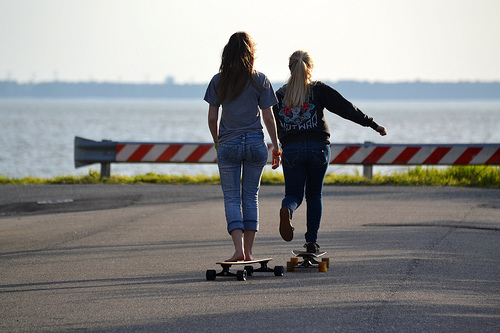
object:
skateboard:
[203, 257, 285, 282]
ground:
[0, 181, 500, 333]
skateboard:
[286, 249, 330, 273]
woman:
[202, 28, 285, 262]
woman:
[272, 48, 389, 254]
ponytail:
[282, 54, 312, 109]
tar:
[0, 181, 498, 331]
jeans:
[215, 131, 271, 235]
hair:
[215, 29, 257, 108]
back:
[213, 69, 265, 132]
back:
[278, 79, 326, 136]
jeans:
[279, 141, 332, 242]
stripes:
[330, 145, 364, 165]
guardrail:
[72, 134, 500, 170]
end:
[71, 134, 92, 170]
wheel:
[205, 269, 217, 281]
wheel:
[236, 269, 247, 281]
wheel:
[273, 265, 285, 276]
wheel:
[243, 265, 254, 276]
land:
[0, 79, 500, 101]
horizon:
[0, 0, 497, 100]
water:
[0, 96, 500, 179]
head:
[286, 49, 316, 80]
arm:
[321, 82, 377, 129]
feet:
[224, 251, 245, 262]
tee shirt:
[202, 68, 281, 147]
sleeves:
[203, 71, 222, 108]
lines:
[140, 144, 171, 162]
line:
[126, 144, 154, 162]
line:
[391, 146, 423, 164]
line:
[452, 146, 484, 164]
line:
[422, 146, 452, 165]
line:
[184, 144, 214, 163]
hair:
[285, 48, 315, 109]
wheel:
[287, 261, 295, 272]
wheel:
[318, 261, 328, 272]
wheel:
[321, 257, 330, 268]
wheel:
[290, 257, 299, 266]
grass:
[0, 162, 500, 188]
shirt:
[272, 79, 379, 149]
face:
[289, 101, 301, 115]